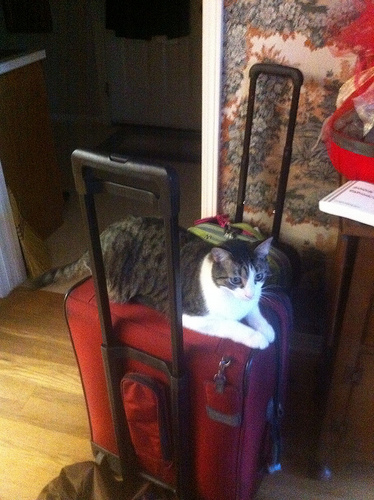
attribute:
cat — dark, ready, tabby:
[25, 212, 280, 356]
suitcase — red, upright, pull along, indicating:
[61, 143, 294, 498]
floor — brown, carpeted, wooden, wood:
[1, 285, 373, 498]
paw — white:
[244, 331, 271, 353]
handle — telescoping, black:
[67, 142, 201, 497]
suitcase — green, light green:
[183, 61, 307, 333]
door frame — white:
[195, 2, 223, 224]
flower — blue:
[223, 25, 252, 94]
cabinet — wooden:
[2, 58, 69, 238]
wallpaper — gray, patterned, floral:
[221, 1, 371, 336]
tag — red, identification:
[188, 212, 231, 231]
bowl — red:
[325, 130, 374, 181]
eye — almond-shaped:
[220, 270, 245, 288]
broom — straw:
[6, 183, 53, 285]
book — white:
[317, 179, 373, 227]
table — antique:
[309, 169, 373, 488]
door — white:
[104, 3, 200, 130]